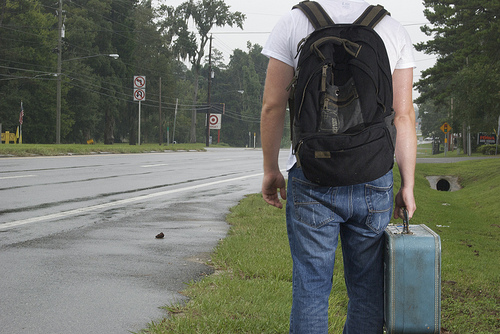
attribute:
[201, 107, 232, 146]
sign — red, white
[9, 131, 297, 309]
road — lined, empty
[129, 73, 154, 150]
road signs — red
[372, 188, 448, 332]
case — blue, green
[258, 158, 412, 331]
jeans — pocketed, blue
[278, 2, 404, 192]
backpack — black, straped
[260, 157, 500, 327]
grass — green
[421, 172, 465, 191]
pipe — gray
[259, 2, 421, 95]
shirt — white